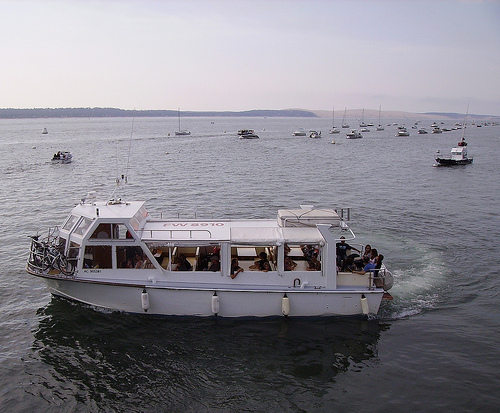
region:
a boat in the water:
[427, 123, 487, 168]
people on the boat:
[346, 240, 387, 273]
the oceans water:
[190, 157, 317, 207]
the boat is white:
[27, 167, 397, 319]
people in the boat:
[235, 253, 269, 277]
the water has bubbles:
[398, 263, 445, 294]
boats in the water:
[304, 120, 366, 144]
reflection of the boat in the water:
[71, 315, 356, 392]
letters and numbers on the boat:
[157, 219, 231, 229]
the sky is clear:
[134, 33, 303, 74]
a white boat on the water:
[13, 199, 393, 314]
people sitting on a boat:
[325, 237, 387, 297]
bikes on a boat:
[33, 226, 83, 276]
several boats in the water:
[293, 111, 484, 164]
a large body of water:
[51, 109, 438, 185]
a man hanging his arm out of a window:
[218, 251, 245, 283]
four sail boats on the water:
[325, 106, 391, 129]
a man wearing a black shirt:
[334, 232, 349, 261]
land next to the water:
[21, 105, 322, 132]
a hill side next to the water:
[312, 109, 441, 125]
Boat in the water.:
[27, 184, 404, 317]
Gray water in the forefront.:
[0, 115, 494, 408]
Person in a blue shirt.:
[354, 253, 373, 273]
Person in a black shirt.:
[334, 230, 352, 257]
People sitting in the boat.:
[360, 240, 386, 272]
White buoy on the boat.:
[279, 295, 291, 316]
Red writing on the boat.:
[157, 218, 229, 228]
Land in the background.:
[1, 103, 498, 118]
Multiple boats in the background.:
[288, 102, 495, 146]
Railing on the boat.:
[135, 224, 216, 241]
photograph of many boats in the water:
[20, 74, 485, 379]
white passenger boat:
[15, 190, 405, 312]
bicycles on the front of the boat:
[29, 224, 75, 284]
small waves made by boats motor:
[395, 236, 448, 321]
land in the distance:
[10, 99, 486, 128]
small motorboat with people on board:
[48, 141, 79, 171]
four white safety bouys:
[134, 286, 387, 317]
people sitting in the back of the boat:
[320, 228, 390, 282]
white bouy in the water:
[30, 120, 57, 140]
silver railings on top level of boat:
[132, 206, 214, 239]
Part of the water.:
[176, 154, 272, 196]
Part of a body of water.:
[175, 152, 314, 192]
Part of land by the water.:
[54, 110, 87, 115]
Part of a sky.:
[88, 30, 193, 71]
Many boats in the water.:
[212, 91, 382, 168]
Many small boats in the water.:
[228, 101, 373, 152]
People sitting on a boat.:
[357, 237, 387, 270]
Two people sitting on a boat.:
[360, 237, 385, 269]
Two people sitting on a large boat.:
[359, 233, 385, 271]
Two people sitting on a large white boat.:
[361, 237, 388, 280]